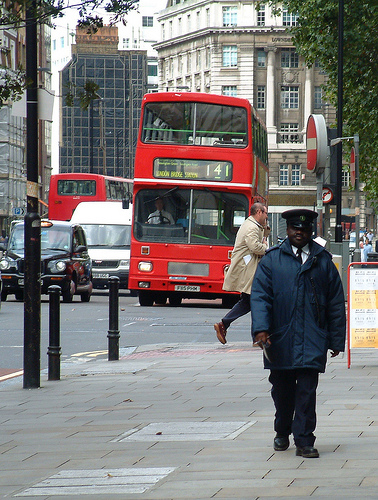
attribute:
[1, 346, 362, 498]
sidewalk — stone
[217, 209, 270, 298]
coat — tan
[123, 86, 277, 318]
bus — double decker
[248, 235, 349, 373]
coat — blue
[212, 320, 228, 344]
shoe — brown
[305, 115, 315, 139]
edge — red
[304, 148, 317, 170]
edge — red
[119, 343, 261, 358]
tile — pink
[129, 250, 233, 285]
headlight — oblong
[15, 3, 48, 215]
pole — tall, black, metal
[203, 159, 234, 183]
bus — double decker, red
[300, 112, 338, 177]
sign — red, white, round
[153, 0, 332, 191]
building — tall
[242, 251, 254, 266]
paper — white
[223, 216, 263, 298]
coat — tan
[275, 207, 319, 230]
hat — black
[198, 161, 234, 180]
number — neon green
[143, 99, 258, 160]
window — top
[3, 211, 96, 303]
bentley — black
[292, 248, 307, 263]
tie — black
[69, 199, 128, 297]
van — white